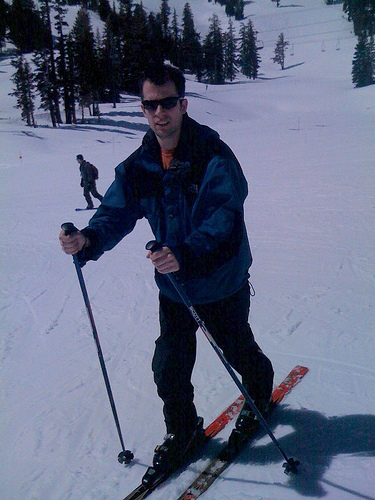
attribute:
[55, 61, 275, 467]
person — walking, distant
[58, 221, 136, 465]
pole — black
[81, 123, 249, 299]
jacket — blue, heavyweight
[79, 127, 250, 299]
suit — blue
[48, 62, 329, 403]
jacket — orange 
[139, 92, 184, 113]
goggles — black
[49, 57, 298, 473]
person — looking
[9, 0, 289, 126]
trees — pine 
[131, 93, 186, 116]
eyeglass — black 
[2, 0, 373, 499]
snow — full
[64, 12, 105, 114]
tree — pine 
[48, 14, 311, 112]
tree — sbackground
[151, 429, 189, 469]
shoe — black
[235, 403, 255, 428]
shoe — black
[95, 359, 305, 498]
ski — red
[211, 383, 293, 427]
skis — red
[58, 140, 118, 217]
person — snowboarding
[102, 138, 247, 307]
jacket — blue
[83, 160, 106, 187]
back — skier's